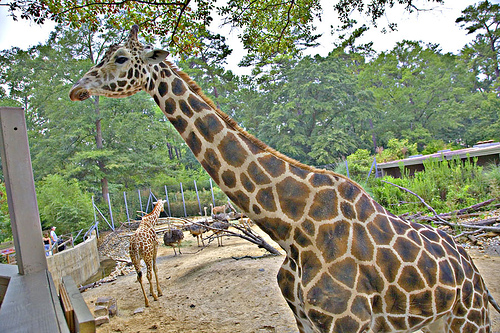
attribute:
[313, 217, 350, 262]
spot — black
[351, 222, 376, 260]
spot — brown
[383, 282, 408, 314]
spot — black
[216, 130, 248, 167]
spot — brown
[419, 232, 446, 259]
spot — black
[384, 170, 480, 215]
weeds — overgrown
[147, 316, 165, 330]
rock — part